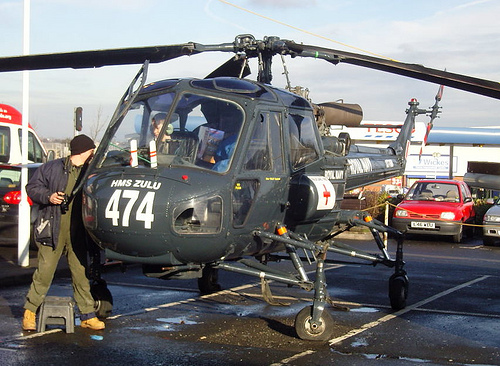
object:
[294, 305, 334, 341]
tire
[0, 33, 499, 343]
helicopter